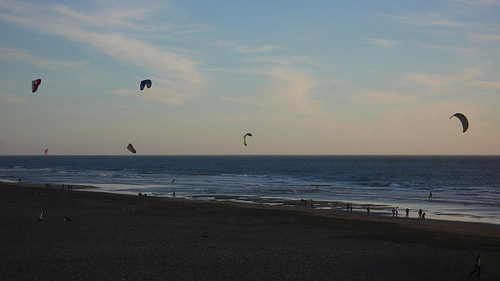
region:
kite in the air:
[451, 110, 471, 132]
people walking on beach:
[338, 201, 436, 219]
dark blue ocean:
[0, 149, 499, 222]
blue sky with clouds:
[3, 4, 498, 151]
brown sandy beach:
[1, 185, 496, 280]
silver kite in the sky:
[238, 129, 258, 148]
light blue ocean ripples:
[197, 172, 369, 194]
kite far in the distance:
[41, 148, 53, 158]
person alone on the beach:
[36, 208, 47, 223]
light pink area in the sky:
[366, 117, 455, 155]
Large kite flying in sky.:
[448, 106, 472, 152]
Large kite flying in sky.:
[213, 115, 270, 171]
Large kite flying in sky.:
[120, 137, 143, 151]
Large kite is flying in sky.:
[133, 65, 165, 99]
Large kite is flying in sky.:
[36, 142, 78, 167]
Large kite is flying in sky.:
[23, 65, 58, 110]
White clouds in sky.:
[118, 22, 203, 94]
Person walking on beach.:
[466, 248, 497, 275]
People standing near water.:
[413, 196, 440, 246]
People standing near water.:
[335, 197, 377, 229]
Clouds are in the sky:
[3, 6, 493, 150]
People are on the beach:
[273, 191, 498, 277]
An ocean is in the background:
[5, 145, 495, 215]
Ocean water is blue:
[5, 146, 495, 208]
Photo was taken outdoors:
[0, 6, 495, 276]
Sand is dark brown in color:
[0, 195, 497, 275]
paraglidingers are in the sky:
[6, 55, 496, 200]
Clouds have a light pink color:
[246, 68, 499, 153]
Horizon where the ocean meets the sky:
[1, 146, 498, 169]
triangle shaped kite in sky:
[29, 77, 44, 94]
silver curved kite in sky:
[238, 131, 256, 146]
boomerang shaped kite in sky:
[452, 110, 471, 135]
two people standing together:
[343, 200, 355, 212]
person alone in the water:
[428, 189, 435, 199]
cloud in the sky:
[46, 18, 197, 75]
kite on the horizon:
[39, 148, 53, 158]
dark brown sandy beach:
[0, 185, 497, 280]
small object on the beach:
[63, 212, 73, 225]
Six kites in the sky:
[19, 58, 480, 195]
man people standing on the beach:
[283, 188, 440, 228]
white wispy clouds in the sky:
[33, 14, 488, 155]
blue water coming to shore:
[11, 144, 499, 224]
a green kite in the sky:
[238, 120, 263, 155]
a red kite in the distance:
[39, 143, 63, 164]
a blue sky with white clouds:
[3, 5, 498, 155]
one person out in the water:
[423, 186, 440, 201]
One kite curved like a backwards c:
[432, 89, 478, 144]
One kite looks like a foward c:
[235, 123, 269, 162]